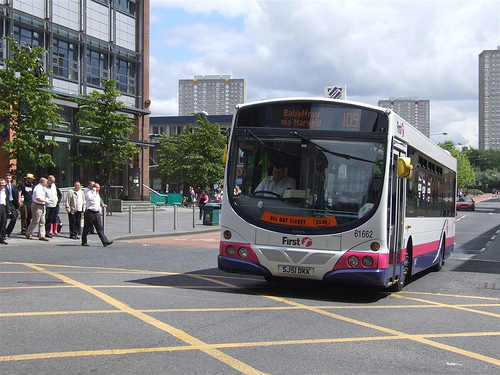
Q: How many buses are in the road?
A: 1.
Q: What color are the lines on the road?
A: Yellow.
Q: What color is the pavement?
A: Black.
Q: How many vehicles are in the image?
A: 2.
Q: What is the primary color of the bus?
A: White.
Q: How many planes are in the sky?
A: 0.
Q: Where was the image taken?
A: At a bus stop.